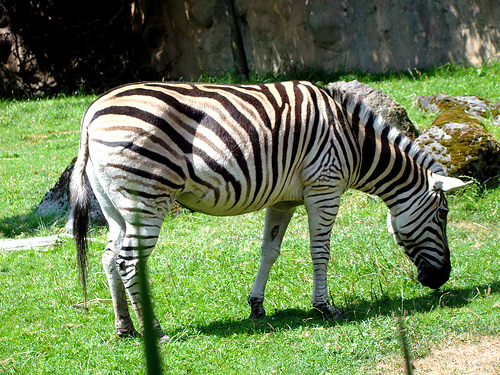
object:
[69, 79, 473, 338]
zebra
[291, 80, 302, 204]
stripe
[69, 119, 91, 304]
tail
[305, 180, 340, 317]
leg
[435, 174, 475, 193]
ear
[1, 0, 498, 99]
wall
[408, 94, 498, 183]
rock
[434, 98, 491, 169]
moss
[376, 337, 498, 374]
grass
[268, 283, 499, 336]
shadow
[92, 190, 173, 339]
back leg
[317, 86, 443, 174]
mane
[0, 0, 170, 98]
shadow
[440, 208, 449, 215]
eye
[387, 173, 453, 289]
head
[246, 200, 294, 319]
leg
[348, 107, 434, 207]
neck